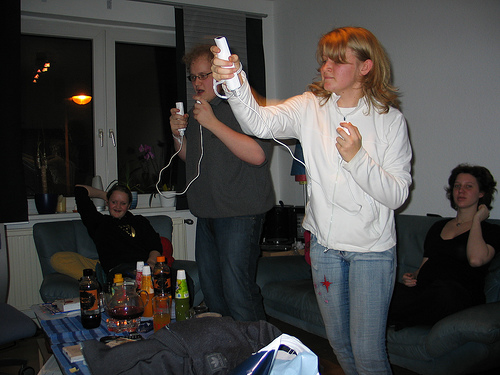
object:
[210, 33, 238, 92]
remotes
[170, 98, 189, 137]
remotes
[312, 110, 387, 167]
hand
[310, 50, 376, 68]
glasses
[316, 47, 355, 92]
face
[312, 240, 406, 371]
jeans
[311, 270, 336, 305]
designs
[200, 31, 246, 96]
controller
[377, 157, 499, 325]
woman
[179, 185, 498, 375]
couch